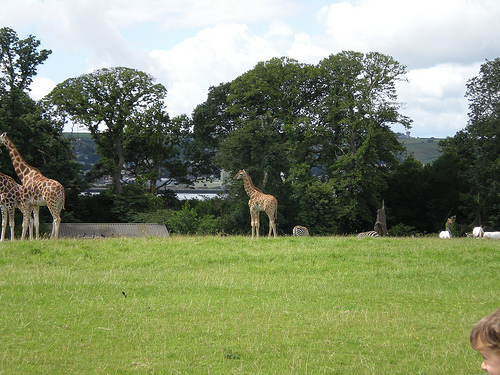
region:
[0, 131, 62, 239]
a tall brown and tan spotted giraffe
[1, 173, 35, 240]
a tall brown and tan spotted giraffe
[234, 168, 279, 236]
a tall brown and tan spotted giraffe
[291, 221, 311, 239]
a black and white zebra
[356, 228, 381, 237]
a black and white zebra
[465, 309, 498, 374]
the head of a little kid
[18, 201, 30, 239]
the leg of a giraffe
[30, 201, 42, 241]
the leg of a giraffe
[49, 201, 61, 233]
the leg of a giraffe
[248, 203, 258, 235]
the leg of a giraffe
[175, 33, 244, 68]
fluffy white cloud in the sky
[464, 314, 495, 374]
a child watching the giraffes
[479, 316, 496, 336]
brown hair on a head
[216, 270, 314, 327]
green grass in an enclosure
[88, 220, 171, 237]
a small stone wall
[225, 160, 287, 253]
a giraffe standing under a tree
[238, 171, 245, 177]
eye of the giraffe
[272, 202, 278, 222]
long tail on the giraffe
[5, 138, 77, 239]
two giraffes standing together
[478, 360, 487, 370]
nose on a face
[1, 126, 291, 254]
Giraffes standing in a field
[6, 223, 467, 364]
Flat grassy green field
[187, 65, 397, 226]
Dense dark trees and foilage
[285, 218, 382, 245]
zebras grazing near the trees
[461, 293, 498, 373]
Little boy watching animals on a field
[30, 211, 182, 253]
Building with a grey roof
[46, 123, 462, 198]
Country landscape behind field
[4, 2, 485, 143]
Cloudy blue skies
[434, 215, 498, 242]
White animals in a field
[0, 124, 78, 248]
Two giraffes standing together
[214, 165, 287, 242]
Young giraffe standing in field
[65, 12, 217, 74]
Sky full of clouds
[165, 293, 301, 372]
The grass is short and green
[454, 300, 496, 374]
The boy is looking in the field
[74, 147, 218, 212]
Buildings in the background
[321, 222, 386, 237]
Zebra grazing in the field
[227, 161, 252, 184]
Giraffe is looking to the left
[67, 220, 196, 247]
Roof of a building in background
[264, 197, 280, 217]
The giraffe has a long tail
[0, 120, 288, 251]
three giraffes are in a field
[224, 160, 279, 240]
giraffe is eating from a tree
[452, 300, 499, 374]
head of a kid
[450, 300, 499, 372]
kid has blond hair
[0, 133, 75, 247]
giraffes stand on side of tree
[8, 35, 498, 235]
trees behind a green field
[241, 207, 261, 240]
front legs of giraffe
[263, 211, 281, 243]
back legs of giraffe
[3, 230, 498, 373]
field is covered with grass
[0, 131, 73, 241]
a tall giraffe